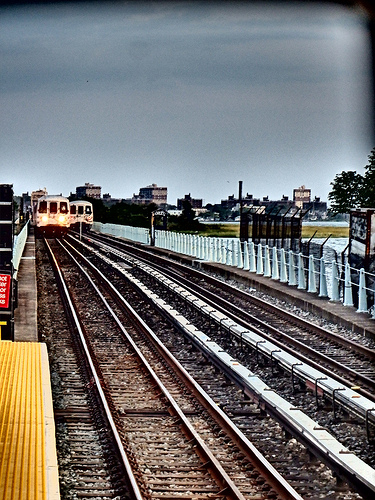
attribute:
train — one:
[35, 198, 70, 236]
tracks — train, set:
[256, 298, 342, 368]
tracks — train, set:
[107, 410, 239, 495]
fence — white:
[99, 220, 364, 310]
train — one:
[33, 193, 70, 230]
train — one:
[70, 199, 95, 228]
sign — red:
[0, 271, 13, 309]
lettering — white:
[0, 282, 8, 286]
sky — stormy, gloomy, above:
[12, 14, 359, 163]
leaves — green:
[343, 178, 353, 189]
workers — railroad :
[3, 236, 45, 338]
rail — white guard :
[98, 215, 243, 266]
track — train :
[52, 222, 322, 478]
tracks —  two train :
[60, 229, 327, 458]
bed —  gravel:
[3, 207, 15, 253]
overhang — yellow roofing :
[4, 323, 59, 497]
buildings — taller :
[75, 175, 328, 226]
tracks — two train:
[43, 231, 335, 427]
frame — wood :
[37, 235, 64, 305]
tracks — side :
[110, 318, 246, 475]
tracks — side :
[67, 249, 227, 446]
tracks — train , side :
[83, 254, 297, 450]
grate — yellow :
[2, 323, 70, 497]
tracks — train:
[142, 316, 356, 478]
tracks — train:
[105, 307, 359, 496]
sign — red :
[0, 268, 12, 306]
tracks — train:
[78, 250, 348, 480]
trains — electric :
[30, 188, 97, 243]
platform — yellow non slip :
[7, 178, 45, 345]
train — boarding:
[27, 193, 102, 237]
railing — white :
[99, 218, 362, 311]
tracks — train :
[49, 235, 355, 491]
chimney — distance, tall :
[237, 176, 244, 196]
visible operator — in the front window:
[59, 198, 67, 212]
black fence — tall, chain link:
[237, 200, 304, 255]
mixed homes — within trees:
[227, 201, 331, 222]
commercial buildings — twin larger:
[75, 182, 168, 204]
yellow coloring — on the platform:
[0, 339, 48, 497]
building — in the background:
[134, 182, 166, 212]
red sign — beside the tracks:
[0, 273, 9, 309]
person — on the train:
[59, 201, 67, 212]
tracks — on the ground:
[44, 239, 331, 498]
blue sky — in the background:
[4, 4, 317, 155]